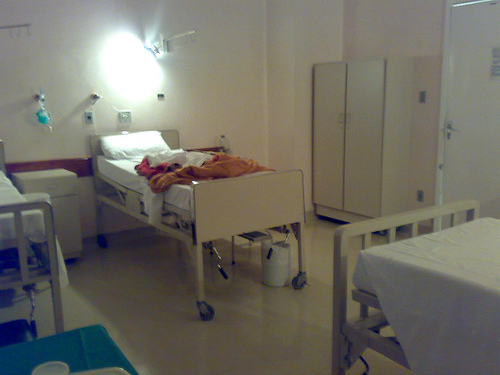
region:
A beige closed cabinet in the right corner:
[308, 54, 413, 228]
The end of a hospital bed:
[326, 193, 499, 373]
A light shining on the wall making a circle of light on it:
[67, 25, 214, 110]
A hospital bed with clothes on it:
[84, 123, 316, 322]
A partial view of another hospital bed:
[0, 140, 83, 340]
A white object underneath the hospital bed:
[261, 240, 292, 293]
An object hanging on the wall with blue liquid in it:
[31, 83, 63, 131]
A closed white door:
[424, 8, 499, 229]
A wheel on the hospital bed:
[185, 294, 232, 336]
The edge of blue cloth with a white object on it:
[1, 321, 146, 373]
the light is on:
[85, 15, 181, 115]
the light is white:
[80, 12, 181, 142]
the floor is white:
[112, 266, 165, 341]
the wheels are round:
[158, 283, 231, 330]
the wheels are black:
[176, 286, 229, 341]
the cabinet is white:
[302, 16, 417, 228]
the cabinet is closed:
[307, 35, 403, 232]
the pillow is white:
[92, 110, 183, 162]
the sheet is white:
[356, 208, 486, 370]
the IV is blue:
[18, 93, 66, 140]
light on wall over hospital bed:
[93, 19, 198, 110]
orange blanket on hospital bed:
[133, 149, 273, 184]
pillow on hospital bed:
[98, 128, 169, 153]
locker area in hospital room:
[311, 48, 405, 237]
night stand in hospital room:
[5, 161, 89, 266]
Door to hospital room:
[439, 9, 497, 240]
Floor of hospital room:
[86, 251, 313, 368]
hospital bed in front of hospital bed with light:
[331, 194, 498, 369]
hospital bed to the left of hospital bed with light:
[3, 170, 76, 325]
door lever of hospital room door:
[440, 116, 457, 144]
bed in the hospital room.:
[91, 128, 311, 318]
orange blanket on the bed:
[148, 154, 261, 195]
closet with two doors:
[311, 57, 412, 223]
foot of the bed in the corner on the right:
[333, 200, 498, 370]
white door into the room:
[436, 1, 499, 226]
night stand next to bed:
[11, 167, 83, 265]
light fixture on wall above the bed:
[143, 28, 195, 63]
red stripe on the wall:
[6, 155, 93, 180]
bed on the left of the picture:
[0, 148, 72, 331]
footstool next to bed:
[229, 228, 272, 265]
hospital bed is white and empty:
[108, 135, 318, 308]